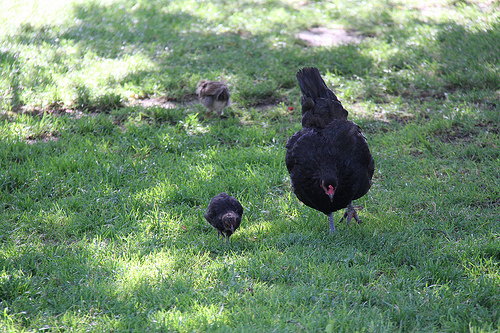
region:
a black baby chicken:
[202, 176, 248, 271]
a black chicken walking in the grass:
[275, 55, 400, 240]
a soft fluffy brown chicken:
[193, 68, 233, 119]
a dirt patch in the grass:
[128, 78, 198, 111]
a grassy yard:
[3, 3, 497, 332]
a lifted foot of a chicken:
[341, 207, 367, 229]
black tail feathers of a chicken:
[292, 60, 348, 122]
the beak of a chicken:
[327, 191, 335, 200]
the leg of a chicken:
[326, 212, 337, 236]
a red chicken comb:
[326, 182, 333, 195]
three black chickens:
[131, 46, 406, 260]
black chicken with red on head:
[271, 47, 392, 256]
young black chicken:
[185, 180, 260, 247]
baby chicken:
[188, 71, 250, 121]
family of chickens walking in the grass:
[82, 38, 412, 283]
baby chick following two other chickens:
[94, 55, 421, 282]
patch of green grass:
[358, 247, 486, 319]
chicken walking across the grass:
[263, 56, 401, 238]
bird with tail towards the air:
[275, 55, 430, 262]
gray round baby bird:
[173, 69, 243, 130]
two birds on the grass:
[185, 71, 425, 253]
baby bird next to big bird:
[176, 168, 255, 245]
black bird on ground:
[199, 163, 271, 236]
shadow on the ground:
[251, 236, 344, 302]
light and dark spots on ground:
[97, 206, 189, 291]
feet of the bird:
[311, 202, 368, 251]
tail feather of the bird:
[287, 44, 358, 121]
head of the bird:
[301, 157, 365, 207]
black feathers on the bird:
[305, 131, 362, 158]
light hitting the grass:
[3, 6, 68, 31]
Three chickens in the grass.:
[159, 55, 377, 261]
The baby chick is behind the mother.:
[172, 61, 238, 120]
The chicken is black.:
[266, 75, 384, 228]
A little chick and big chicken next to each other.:
[187, 94, 378, 273]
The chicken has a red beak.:
[323, 178, 337, 197]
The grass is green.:
[38, 192, 299, 303]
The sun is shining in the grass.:
[98, 16, 319, 81]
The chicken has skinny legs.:
[321, 203, 371, 237]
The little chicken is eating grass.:
[178, 186, 257, 256]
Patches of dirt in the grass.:
[33, 93, 101, 148]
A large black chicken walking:
[273, 61, 383, 239]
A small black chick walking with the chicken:
[200, 178, 252, 247]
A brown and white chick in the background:
[187, 70, 240, 123]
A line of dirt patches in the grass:
[15, 68, 497, 141]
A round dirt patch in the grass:
[286, 16, 374, 54]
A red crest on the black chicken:
[322, 180, 337, 197]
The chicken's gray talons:
[317, 199, 366, 235]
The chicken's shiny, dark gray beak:
[327, 192, 337, 203]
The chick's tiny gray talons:
[214, 229, 233, 253]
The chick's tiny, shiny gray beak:
[229, 224, 234, 233]